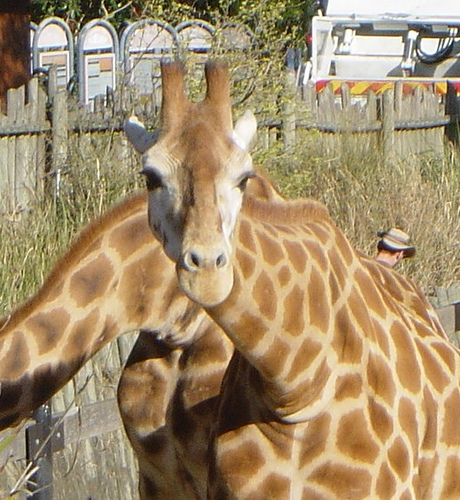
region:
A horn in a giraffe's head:
[163, 60, 185, 105]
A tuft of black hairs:
[207, 58, 228, 67]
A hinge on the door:
[27, 424, 61, 449]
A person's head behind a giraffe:
[378, 227, 412, 260]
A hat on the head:
[384, 228, 412, 248]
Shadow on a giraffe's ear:
[133, 127, 148, 146]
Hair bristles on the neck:
[90, 222, 103, 231]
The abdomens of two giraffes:
[148, 417, 270, 480]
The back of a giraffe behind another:
[256, 184, 269, 197]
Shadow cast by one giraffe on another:
[159, 434, 205, 462]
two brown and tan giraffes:
[3, 56, 457, 496]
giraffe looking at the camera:
[121, 58, 450, 491]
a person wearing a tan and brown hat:
[368, 218, 417, 273]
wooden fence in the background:
[6, 282, 458, 489]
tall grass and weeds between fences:
[2, 159, 458, 289]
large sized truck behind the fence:
[305, 0, 458, 101]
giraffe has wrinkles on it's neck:
[123, 63, 390, 436]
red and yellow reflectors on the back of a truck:
[307, 0, 458, 105]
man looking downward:
[373, 224, 417, 268]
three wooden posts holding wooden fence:
[50, 83, 398, 175]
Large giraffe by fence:
[151, 67, 359, 495]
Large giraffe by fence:
[13, 220, 165, 431]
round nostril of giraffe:
[174, 247, 216, 276]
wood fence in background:
[23, 98, 400, 172]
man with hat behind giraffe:
[364, 221, 421, 277]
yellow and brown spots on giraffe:
[292, 295, 366, 363]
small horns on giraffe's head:
[145, 31, 239, 94]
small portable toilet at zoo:
[35, 21, 66, 111]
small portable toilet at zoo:
[181, 9, 215, 83]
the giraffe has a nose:
[166, 241, 236, 302]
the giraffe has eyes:
[134, 158, 256, 207]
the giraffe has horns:
[154, 50, 243, 96]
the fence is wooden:
[328, 99, 431, 146]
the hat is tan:
[356, 224, 427, 253]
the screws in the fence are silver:
[26, 430, 68, 449]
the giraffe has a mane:
[261, 188, 313, 224]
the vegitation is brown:
[325, 152, 441, 206]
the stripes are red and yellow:
[349, 78, 384, 91]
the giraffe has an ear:
[236, 111, 263, 139]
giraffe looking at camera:
[99, 41, 459, 493]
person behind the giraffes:
[375, 220, 419, 269]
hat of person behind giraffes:
[383, 225, 414, 253]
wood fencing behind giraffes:
[10, 293, 456, 498]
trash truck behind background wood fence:
[298, 10, 459, 98]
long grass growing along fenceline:
[3, 142, 445, 314]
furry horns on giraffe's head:
[153, 46, 235, 110]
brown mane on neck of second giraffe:
[7, 184, 152, 331]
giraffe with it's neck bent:
[5, 184, 215, 494]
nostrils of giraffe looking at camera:
[180, 246, 226, 278]